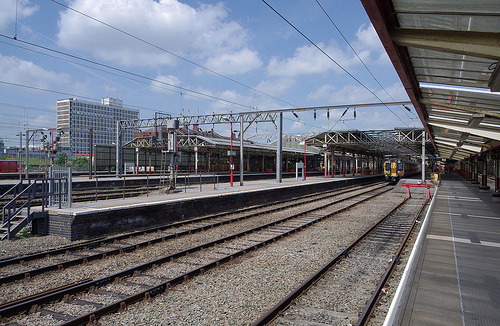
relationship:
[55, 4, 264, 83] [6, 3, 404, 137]
clouds are in sky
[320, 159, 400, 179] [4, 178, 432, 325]
barricade by train tracks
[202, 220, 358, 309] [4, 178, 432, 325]
gravel by train tracks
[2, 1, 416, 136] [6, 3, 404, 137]
cables are in sky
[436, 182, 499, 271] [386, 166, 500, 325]
lines are on platform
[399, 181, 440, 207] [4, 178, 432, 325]
bench on train tracks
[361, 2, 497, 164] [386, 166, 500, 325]
station cover over platform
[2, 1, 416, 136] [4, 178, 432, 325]
cables are over train tracks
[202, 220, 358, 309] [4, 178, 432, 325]
gravel between train tracks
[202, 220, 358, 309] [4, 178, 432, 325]
gravel next to train tracks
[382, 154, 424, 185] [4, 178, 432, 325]
train car on train tracks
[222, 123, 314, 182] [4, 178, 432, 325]
poles are by train tracks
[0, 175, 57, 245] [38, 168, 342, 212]
steps lead to platform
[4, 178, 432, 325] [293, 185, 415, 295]
train tracks on ground